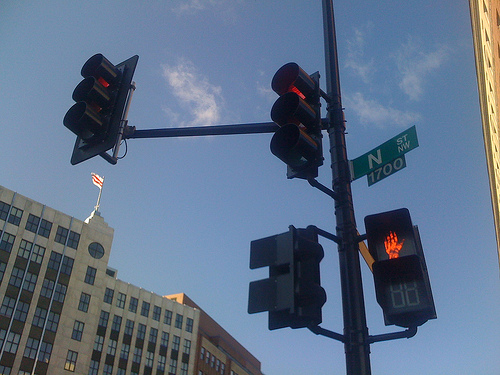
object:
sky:
[2, 2, 500, 373]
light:
[270, 62, 325, 179]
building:
[0, 182, 267, 373]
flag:
[91, 172, 105, 190]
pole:
[323, 2, 371, 375]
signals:
[363, 207, 440, 328]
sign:
[348, 125, 418, 179]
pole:
[97, 175, 105, 205]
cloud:
[158, 45, 443, 138]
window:
[88, 241, 104, 258]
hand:
[383, 231, 404, 260]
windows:
[185, 318, 193, 332]